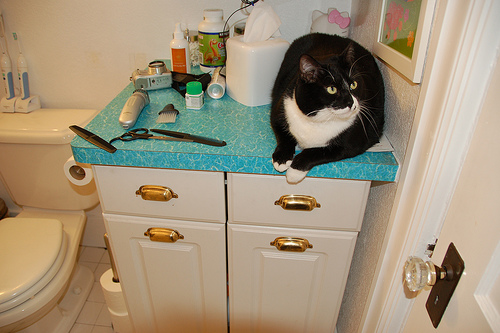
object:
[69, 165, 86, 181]
roll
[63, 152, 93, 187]
toilet paper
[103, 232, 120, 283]
holder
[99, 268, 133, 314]
paper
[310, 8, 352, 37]
kitty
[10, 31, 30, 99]
electric toothbrushes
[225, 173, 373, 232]
drawer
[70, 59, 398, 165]
counter top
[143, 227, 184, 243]
golden handle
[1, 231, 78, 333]
bowl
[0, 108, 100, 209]
tank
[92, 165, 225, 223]
drawer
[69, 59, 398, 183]
counter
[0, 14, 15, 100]
toothbrush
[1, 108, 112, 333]
toilet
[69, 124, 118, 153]
comb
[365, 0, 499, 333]
door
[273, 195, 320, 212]
drawer pulls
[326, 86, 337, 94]
eye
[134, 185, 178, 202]
handle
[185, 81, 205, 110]
bottle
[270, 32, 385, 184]
cat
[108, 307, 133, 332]
toilet paper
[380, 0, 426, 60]
picture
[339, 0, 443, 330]
wall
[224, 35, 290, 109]
box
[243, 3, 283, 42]
tissues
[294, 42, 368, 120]
kitty's head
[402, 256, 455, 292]
door handle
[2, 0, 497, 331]
room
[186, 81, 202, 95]
lid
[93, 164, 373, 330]
cabinet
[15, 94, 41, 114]
stands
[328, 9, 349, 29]
bow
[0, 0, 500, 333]
bathroom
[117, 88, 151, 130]
items